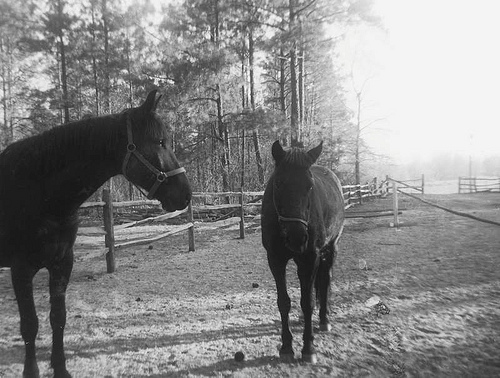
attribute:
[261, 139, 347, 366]
horse — small, watching, looking, black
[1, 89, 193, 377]
horse — large, brown, looking, dark, black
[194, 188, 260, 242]
fence — wood, wooden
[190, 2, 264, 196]
trees — pine trees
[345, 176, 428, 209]
fence — wooden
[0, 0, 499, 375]
image — black, white, black and white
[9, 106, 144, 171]
mane — black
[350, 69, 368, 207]
tree — dead